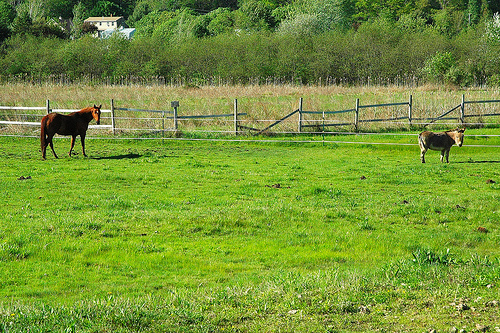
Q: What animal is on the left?
A: A horse.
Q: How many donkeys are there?
A: One.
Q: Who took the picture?
A: The photographer.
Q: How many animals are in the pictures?
A: 2.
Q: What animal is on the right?
A: A donkey.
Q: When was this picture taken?
A: Daytime.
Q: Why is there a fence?
A: To keep the animals in it.